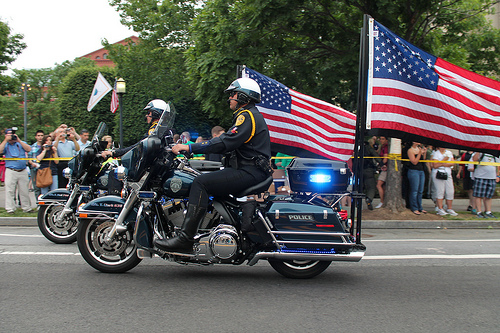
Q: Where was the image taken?
A: It was taken at the road.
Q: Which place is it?
A: It is a road.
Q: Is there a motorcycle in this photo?
A: Yes, there is a motorcycle.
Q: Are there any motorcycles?
A: Yes, there is a motorcycle.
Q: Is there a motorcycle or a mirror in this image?
A: Yes, there is a motorcycle.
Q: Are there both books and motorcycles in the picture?
A: No, there is a motorcycle but no books.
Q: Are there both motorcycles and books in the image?
A: No, there is a motorcycle but no books.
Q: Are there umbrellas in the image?
A: No, there are no umbrellas.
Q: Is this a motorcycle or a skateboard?
A: This is a motorcycle.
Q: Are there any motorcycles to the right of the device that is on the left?
A: Yes, there is a motorcycle to the right of the camera.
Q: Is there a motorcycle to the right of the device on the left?
A: Yes, there is a motorcycle to the right of the camera.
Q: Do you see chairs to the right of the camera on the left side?
A: No, there is a motorcycle to the right of the camera.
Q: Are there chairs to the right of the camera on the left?
A: No, there is a motorcycle to the right of the camera.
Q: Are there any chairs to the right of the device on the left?
A: No, there is a motorcycle to the right of the camera.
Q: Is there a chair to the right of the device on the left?
A: No, there is a motorcycle to the right of the camera.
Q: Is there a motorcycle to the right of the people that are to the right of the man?
A: Yes, there is a motorcycle to the right of the people.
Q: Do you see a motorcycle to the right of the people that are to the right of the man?
A: Yes, there is a motorcycle to the right of the people.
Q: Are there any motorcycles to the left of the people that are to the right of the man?
A: No, the motorcycle is to the right of the people.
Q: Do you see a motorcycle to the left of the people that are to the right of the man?
A: No, the motorcycle is to the right of the people.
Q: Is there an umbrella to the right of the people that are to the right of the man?
A: No, there is a motorcycle to the right of the people.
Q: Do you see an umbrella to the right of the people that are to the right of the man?
A: No, there is a motorcycle to the right of the people.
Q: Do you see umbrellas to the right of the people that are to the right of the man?
A: No, there is a motorcycle to the right of the people.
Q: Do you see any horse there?
A: No, there are no horses.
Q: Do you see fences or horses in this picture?
A: No, there are no horses or fences.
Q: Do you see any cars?
A: No, there are no cars.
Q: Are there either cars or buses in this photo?
A: No, there are no cars or buses.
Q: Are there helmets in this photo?
A: Yes, there is a helmet.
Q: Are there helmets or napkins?
A: Yes, there is a helmet.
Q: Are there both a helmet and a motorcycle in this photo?
A: Yes, there are both a helmet and a motorcycle.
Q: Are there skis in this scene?
A: No, there are no skis.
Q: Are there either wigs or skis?
A: No, there are no skis or wigs.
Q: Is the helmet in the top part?
A: Yes, the helmet is in the top of the image.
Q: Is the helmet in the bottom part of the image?
A: No, the helmet is in the top of the image.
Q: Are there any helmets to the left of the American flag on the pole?
A: Yes, there is a helmet to the left of the American flag.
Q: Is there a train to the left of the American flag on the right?
A: No, there is a helmet to the left of the American flag.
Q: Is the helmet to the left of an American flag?
A: Yes, the helmet is to the left of an American flag.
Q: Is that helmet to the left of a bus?
A: No, the helmet is to the left of an American flag.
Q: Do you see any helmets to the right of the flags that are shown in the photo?
A: Yes, there is a helmet to the right of the flags.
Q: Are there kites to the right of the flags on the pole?
A: No, there is a helmet to the right of the flags.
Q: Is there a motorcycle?
A: Yes, there are motorcycles.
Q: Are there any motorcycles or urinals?
A: Yes, there are motorcycles.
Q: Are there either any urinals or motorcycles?
A: Yes, there are motorcycles.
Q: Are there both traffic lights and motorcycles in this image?
A: No, there are motorcycles but no traffic lights.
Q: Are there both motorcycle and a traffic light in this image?
A: No, there are motorcycles but no traffic lights.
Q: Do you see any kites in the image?
A: No, there are no kites.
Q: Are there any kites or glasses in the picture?
A: No, there are no kites or glasses.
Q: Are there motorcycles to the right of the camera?
A: Yes, there are motorcycles to the right of the camera.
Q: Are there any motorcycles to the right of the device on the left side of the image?
A: Yes, there are motorcycles to the right of the camera.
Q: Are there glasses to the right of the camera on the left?
A: No, there are motorcycles to the right of the camera.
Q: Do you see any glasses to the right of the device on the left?
A: No, there are motorcycles to the right of the camera.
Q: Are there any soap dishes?
A: No, there are no soap dishes.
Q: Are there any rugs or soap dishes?
A: No, there are no soap dishes or rugs.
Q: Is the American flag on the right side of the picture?
A: Yes, the American flag is on the right of the image.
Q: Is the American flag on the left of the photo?
A: No, the American flag is on the right of the image.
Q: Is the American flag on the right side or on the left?
A: The American flag is on the right of the image.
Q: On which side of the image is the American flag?
A: The American flag is on the right of the image.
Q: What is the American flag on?
A: The American flag is on the pole.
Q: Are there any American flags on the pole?
A: Yes, there is an American flag on the pole.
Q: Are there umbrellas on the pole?
A: No, there is an American flag on the pole.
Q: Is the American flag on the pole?
A: Yes, the American flag is on the pole.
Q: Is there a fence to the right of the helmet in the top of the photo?
A: No, there is an American flag to the right of the helmet.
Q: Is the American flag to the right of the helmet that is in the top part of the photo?
A: Yes, the American flag is to the right of the helmet.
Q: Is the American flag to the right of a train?
A: No, the American flag is to the right of the helmet.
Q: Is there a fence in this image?
A: No, there are no fences.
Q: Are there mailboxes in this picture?
A: No, there are no mailboxes.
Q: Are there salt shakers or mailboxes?
A: No, there are no mailboxes or salt shakers.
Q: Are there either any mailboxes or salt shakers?
A: No, there are no mailboxes or salt shakers.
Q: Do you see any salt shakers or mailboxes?
A: No, there are no mailboxes or salt shakers.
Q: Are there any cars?
A: No, there are no cars.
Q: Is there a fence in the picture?
A: No, there are no fences.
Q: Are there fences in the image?
A: No, there are no fences.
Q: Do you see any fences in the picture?
A: No, there are no fences.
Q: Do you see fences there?
A: No, there are no fences.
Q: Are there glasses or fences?
A: No, there are no fences or glasses.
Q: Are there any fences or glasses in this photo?
A: No, there are no fences or glasses.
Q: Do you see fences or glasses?
A: No, there are no fences or glasses.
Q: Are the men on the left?
A: Yes, the men are on the left of the image.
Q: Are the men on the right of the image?
A: No, the men are on the left of the image.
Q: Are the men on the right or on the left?
A: The men are on the left of the image.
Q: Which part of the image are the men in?
A: The men are on the left of the image.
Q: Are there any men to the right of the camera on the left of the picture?
A: Yes, there are men to the right of the camera.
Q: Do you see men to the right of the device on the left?
A: Yes, there are men to the right of the camera.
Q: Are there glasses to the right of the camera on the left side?
A: No, there are men to the right of the camera.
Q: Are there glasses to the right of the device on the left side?
A: No, there are men to the right of the camera.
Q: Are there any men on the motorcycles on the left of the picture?
A: Yes, there are men on the motorbikes.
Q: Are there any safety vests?
A: No, there are no safety vests.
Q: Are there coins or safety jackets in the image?
A: No, there are no safety jackets or coins.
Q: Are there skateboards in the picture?
A: No, there are no skateboards.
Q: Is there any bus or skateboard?
A: No, there are no skateboards or buses.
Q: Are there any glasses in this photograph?
A: No, there are no glasses.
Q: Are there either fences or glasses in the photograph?
A: No, there are no glasses or fences.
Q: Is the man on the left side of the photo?
A: Yes, the man is on the left of the image.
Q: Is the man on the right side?
A: No, the man is on the left of the image.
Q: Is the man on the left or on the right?
A: The man is on the left of the image.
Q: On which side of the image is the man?
A: The man is on the left of the image.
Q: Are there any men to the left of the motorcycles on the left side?
A: Yes, there is a man to the left of the motorcycles.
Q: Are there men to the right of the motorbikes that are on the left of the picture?
A: No, the man is to the left of the motorbikes.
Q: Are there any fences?
A: No, there are no fences.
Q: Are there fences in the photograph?
A: No, there are no fences.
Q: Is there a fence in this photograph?
A: No, there are no fences.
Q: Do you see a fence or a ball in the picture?
A: No, there are no fences or balls.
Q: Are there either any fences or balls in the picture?
A: No, there are no fences or balls.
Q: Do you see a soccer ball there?
A: No, there are no soccer balls.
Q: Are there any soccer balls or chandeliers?
A: No, there are no soccer balls or chandeliers.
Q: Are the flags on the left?
A: Yes, the flags are on the left of the image.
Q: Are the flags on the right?
A: No, the flags are on the left of the image.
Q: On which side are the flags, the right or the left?
A: The flags are on the left of the image.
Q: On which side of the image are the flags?
A: The flags are on the left of the image.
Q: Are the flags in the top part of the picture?
A: Yes, the flags are in the top of the image.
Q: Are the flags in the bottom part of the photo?
A: No, the flags are in the top of the image.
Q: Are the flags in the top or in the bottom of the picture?
A: The flags are in the top of the image.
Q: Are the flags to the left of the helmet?
A: Yes, the flags are to the left of the helmet.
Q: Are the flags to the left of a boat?
A: No, the flags are to the left of the helmet.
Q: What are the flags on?
A: The flags are on the pole.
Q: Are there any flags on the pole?
A: Yes, there are flags on the pole.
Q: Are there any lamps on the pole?
A: No, there are flags on the pole.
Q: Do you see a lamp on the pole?
A: No, there are flags on the pole.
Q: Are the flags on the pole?
A: Yes, the flags are on the pole.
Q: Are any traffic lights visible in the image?
A: No, there are no traffic lights.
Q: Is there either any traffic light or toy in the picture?
A: No, there are no traffic lights or toys.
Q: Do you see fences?
A: No, there are no fences.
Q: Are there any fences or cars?
A: No, there are no fences or cars.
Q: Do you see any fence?
A: No, there are no fences.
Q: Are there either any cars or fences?
A: No, there are no fences or cars.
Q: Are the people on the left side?
A: Yes, the people are on the left of the image.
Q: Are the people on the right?
A: No, the people are on the left of the image.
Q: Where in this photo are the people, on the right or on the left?
A: The people are on the left of the image.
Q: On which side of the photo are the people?
A: The people are on the left of the image.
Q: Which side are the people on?
A: The people are on the left of the image.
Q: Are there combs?
A: No, there are no combs.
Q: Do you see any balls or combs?
A: No, there are no combs or balls.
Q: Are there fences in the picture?
A: No, there are no fences.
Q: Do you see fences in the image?
A: No, there are no fences.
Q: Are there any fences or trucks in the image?
A: No, there are no fences or trucks.